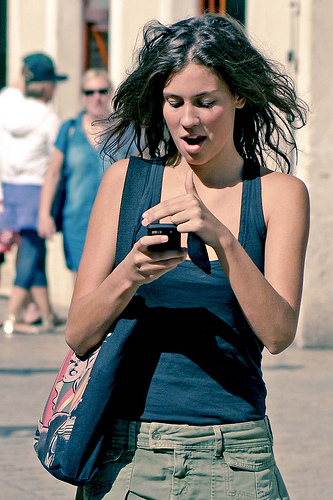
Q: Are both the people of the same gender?
A: Yes, all the people are female.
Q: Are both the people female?
A: Yes, all the people are female.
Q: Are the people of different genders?
A: No, all the people are female.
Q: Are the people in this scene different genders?
A: No, all the people are female.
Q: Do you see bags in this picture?
A: Yes, there is a bag.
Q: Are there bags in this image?
A: Yes, there is a bag.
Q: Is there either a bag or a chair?
A: Yes, there is a bag.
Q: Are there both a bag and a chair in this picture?
A: No, there is a bag but no chairs.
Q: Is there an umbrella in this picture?
A: No, there are no umbrellas.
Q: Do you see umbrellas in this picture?
A: No, there are no umbrellas.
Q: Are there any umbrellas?
A: No, there are no umbrellas.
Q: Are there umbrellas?
A: No, there are no umbrellas.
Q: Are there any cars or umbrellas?
A: No, there are no umbrellas or cars.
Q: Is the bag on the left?
A: Yes, the bag is on the left of the image.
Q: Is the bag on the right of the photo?
A: No, the bag is on the left of the image.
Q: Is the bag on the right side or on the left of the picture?
A: The bag is on the left of the image.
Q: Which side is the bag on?
A: The bag is on the left of the image.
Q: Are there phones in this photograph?
A: Yes, there is a phone.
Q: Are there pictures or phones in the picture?
A: Yes, there is a phone.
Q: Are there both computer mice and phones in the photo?
A: No, there is a phone but no computer mice.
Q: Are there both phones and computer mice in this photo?
A: No, there is a phone but no computer mice.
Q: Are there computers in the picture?
A: No, there are no computers.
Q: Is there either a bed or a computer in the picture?
A: No, there are no computers or beds.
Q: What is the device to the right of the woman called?
A: The device is a phone.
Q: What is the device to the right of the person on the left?
A: The device is a phone.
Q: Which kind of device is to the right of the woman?
A: The device is a phone.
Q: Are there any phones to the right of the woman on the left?
A: Yes, there is a phone to the right of the woman.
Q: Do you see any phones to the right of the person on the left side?
A: Yes, there is a phone to the right of the woman.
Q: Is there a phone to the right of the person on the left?
A: Yes, there is a phone to the right of the woman.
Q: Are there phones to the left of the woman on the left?
A: No, the phone is to the right of the woman.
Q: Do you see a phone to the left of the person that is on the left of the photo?
A: No, the phone is to the right of the woman.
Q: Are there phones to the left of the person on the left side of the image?
A: No, the phone is to the right of the woman.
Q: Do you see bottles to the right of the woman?
A: No, there is a phone to the right of the woman.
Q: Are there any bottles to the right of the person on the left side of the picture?
A: No, there is a phone to the right of the woman.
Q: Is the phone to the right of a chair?
A: No, the phone is to the right of the woman.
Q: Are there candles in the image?
A: No, there are no candles.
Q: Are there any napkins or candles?
A: No, there are no candles or napkins.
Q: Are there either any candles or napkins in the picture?
A: No, there are no candles or napkins.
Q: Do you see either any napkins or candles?
A: No, there are no candles or napkins.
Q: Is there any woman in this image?
A: Yes, there is a woman.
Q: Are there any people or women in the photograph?
A: Yes, there is a woman.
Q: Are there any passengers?
A: No, there are no passengers.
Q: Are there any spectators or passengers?
A: No, there are no passengers or spectators.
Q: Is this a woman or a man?
A: This is a woman.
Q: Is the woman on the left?
A: Yes, the woman is on the left of the image.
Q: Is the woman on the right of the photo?
A: No, the woman is on the left of the image.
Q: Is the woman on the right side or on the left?
A: The woman is on the left of the image.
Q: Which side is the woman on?
A: The woman is on the left of the image.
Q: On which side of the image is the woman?
A: The woman is on the left of the image.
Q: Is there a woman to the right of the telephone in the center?
A: No, the woman is to the left of the phone.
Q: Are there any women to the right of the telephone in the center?
A: No, the woman is to the left of the phone.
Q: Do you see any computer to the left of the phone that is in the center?
A: No, there is a woman to the left of the phone.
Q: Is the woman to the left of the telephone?
A: Yes, the woman is to the left of the telephone.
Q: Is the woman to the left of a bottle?
A: No, the woman is to the left of the telephone.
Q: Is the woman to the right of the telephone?
A: No, the woman is to the left of the telephone.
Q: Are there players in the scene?
A: No, there are no players.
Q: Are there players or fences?
A: No, there are no players or fences.